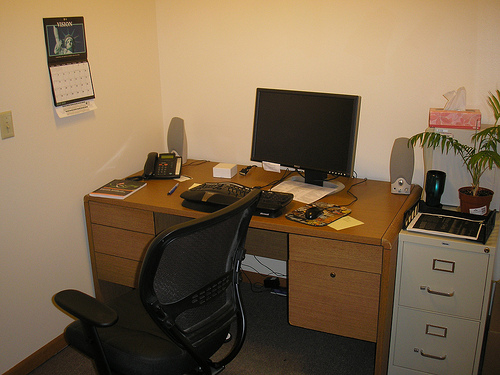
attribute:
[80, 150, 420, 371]
desk — wooden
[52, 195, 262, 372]
chair — ergonomic, black, office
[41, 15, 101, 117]
calendar — monthly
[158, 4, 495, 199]
wall — white, smooth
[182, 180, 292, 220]
computer keyboard — black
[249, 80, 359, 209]
computer monitor — black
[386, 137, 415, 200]
speaker — gray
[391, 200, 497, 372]
filing cabinet — gray, metallic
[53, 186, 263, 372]
swiveling chair — black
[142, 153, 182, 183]
phone — landline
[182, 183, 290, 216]
keyboard — black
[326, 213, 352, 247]
post-it note — yellow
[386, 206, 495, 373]
cabinet — beige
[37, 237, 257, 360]
chair — black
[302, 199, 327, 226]
mouse — black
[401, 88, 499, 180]
plant — small, potted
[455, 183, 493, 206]
flower pot — brown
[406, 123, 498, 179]
leaves — green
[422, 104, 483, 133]
box — pink, white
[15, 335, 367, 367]
carpeting — dark brown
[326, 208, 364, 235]
paper — yellow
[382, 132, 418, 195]
speaker — grey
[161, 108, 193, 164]
speaker — grey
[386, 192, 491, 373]
cabinet — metal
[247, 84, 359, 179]
screen — computer, black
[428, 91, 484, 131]
box — pink, tissues